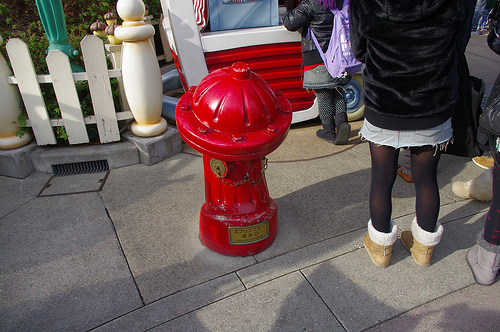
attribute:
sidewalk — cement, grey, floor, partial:
[1, 31, 499, 331]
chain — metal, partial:
[211, 159, 268, 186]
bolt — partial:
[196, 124, 208, 135]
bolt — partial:
[231, 133, 244, 144]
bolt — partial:
[265, 124, 278, 136]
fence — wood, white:
[0, 1, 167, 152]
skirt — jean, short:
[357, 117, 454, 154]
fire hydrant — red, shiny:
[174, 60, 295, 257]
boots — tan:
[361, 216, 443, 267]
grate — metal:
[50, 158, 109, 177]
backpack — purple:
[309, 0, 362, 78]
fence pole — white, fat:
[114, 1, 168, 138]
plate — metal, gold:
[226, 217, 270, 244]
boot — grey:
[466, 226, 499, 287]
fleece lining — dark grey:
[474, 228, 498, 255]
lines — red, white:
[192, 0, 209, 30]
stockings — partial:
[313, 87, 346, 124]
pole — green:
[34, 0, 86, 84]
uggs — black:
[314, 111, 350, 146]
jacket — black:
[346, 2, 475, 118]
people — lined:
[280, 0, 499, 284]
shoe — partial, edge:
[396, 163, 413, 185]